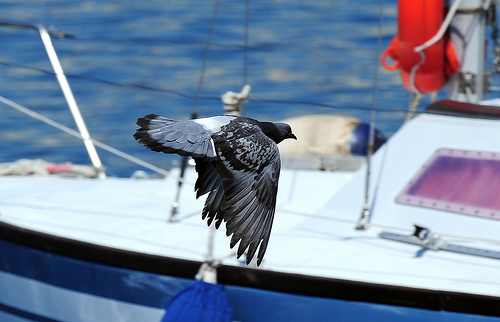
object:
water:
[0, 0, 499, 178]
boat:
[1, 0, 500, 321]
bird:
[133, 113, 298, 267]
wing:
[213, 133, 281, 267]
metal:
[37, 25, 110, 182]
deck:
[0, 168, 498, 296]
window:
[394, 147, 499, 220]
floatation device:
[382, 0, 460, 94]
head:
[276, 122, 298, 141]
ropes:
[168, 1, 221, 222]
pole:
[444, 0, 494, 105]